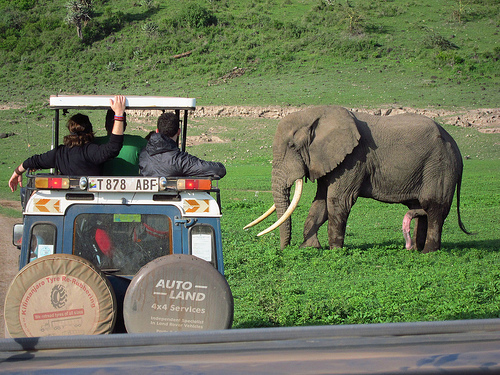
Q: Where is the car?
A: Next to the elephant.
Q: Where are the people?
A: In the car.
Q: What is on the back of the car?
A: Two tires.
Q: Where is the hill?
A: Behind the elephant.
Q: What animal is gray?
A: The elephant.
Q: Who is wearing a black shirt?
A: The person in the car.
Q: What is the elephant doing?
A: Standing.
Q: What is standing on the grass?
A: The elephant.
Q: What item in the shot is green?
A: The grassy hill.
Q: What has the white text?
A: The dirty black spare tire cover.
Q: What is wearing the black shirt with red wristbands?
A: The woman.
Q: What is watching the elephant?
A: The people in the vehicle.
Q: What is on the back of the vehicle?
A: The wheel with the cover.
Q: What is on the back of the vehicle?
A: The covered wheel.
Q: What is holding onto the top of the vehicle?
A: The person.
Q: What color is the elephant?
A: Grey.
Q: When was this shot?
A: Daytime.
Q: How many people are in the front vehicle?
A: 3.